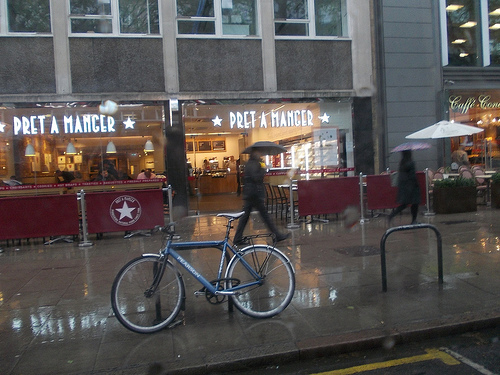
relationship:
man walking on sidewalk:
[233, 149, 288, 246] [0, 195, 499, 374]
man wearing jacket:
[233, 149, 288, 246] [241, 156, 269, 198]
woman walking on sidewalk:
[388, 150, 420, 225] [0, 195, 499, 374]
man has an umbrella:
[233, 149, 288, 246] [241, 141, 288, 155]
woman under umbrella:
[388, 150, 420, 225] [389, 141, 432, 153]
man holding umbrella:
[233, 149, 288, 246] [241, 141, 288, 155]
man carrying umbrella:
[233, 149, 288, 246] [241, 141, 288, 155]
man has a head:
[233, 149, 288, 246] [251, 149, 263, 161]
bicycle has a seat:
[112, 211, 295, 333] [216, 211, 245, 220]